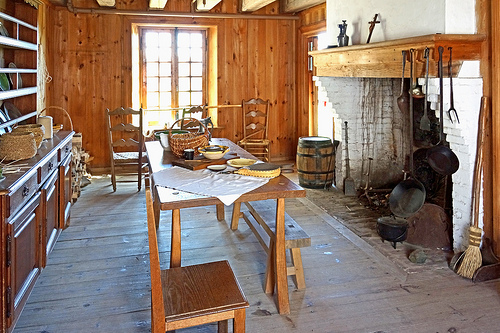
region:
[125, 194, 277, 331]
Small dark brown wooden chair on the ground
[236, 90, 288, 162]
Small dark brown wooden chair on the ground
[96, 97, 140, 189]
Small dark brown wooden chair on the ground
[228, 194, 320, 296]
Small dark brown wooden bench on the ground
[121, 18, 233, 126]
Large window in the wall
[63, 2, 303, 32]
Large metal pole in the wall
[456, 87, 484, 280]
Small broom on the floor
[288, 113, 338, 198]
Wooden and black wiskey barrell on the floor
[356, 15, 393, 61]
Small wooden cross on the mantle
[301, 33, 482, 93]
Large wooden mantle hanging on the wall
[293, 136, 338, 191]
an old wooden barrel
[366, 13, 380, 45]
a crucifix leaning on the wall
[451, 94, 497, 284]
a broom and dustpan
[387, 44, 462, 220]
various tools and cooking utensils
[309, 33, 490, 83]
a wooden fireplace mantle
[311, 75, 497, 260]
white bricked fireplace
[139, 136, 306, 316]
large wooden kitchen table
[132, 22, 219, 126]
large window shining light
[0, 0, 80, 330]
a large china cabnit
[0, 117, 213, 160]
A few baskets sitting out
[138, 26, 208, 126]
the window in the room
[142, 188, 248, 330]
the empty wooden chair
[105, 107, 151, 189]
the empty wooden chair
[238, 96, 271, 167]
the empty wooden chair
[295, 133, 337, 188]
the wooden barrel near the brick wall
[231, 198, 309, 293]
the empty wooden bench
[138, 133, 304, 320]
the long wooden table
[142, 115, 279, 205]
the objects on the wooden table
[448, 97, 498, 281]
the broom and dust pan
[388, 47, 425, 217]
the pan with a very long handle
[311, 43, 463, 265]
Fireplace tools hanging over fireplace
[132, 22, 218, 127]
Window shining light in the room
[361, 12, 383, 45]
Crucifix above the fireplace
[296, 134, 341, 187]
wooden barrel next to the fireplace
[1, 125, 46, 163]
Two baskets resting on cabnit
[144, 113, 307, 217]
Table top with dishes and a basket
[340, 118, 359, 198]
Shovel for fireplace ashes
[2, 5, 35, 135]
Shelving displaying various plates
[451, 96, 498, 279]
broom leaning next to a fireplace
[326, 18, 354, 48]
small sculpture on fireplace mantle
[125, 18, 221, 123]
light is coming through the window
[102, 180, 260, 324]
the chair is empty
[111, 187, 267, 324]
the chair is brown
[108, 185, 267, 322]
the chair is made of wood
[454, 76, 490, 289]
a broom in the corner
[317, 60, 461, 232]
the fire place is off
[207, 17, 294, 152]
the wall is made of wood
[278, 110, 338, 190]
a barrel on the floor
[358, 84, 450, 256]
cast iron pots hanging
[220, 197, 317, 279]
a bench under the table